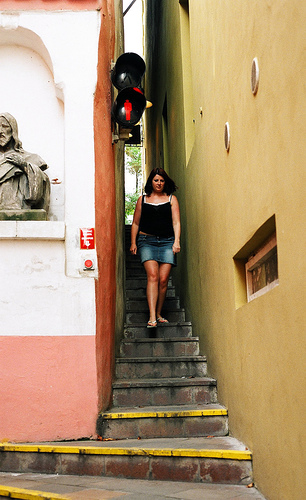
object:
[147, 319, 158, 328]
flip flops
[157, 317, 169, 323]
flip flops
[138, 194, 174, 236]
shirt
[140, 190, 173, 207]
border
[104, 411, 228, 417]
edge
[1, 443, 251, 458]
edge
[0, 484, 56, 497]
edge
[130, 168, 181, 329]
girl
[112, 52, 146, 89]
black balloons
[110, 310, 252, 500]
staircase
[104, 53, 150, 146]
lamp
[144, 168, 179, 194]
hair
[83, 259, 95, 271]
red button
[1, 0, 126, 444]
building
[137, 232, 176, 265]
skirt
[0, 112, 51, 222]
figure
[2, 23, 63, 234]
window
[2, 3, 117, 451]
wall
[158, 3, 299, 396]
wall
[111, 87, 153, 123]
balloon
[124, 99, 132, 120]
man logo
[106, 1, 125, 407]
wall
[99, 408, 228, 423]
edge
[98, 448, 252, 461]
edge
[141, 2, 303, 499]
building